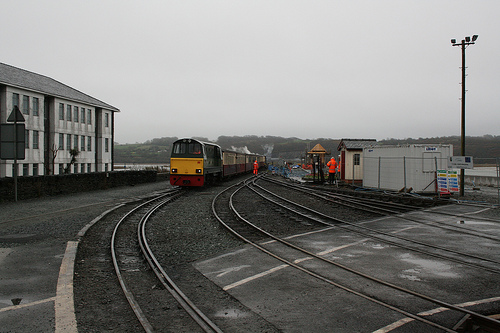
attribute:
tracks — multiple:
[68, 168, 498, 324]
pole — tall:
[459, 41, 467, 195]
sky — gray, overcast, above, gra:
[7, 2, 499, 140]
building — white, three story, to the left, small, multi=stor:
[4, 60, 122, 181]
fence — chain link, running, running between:
[0, 163, 164, 202]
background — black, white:
[3, 5, 497, 219]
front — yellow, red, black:
[166, 135, 205, 189]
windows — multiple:
[4, 87, 117, 175]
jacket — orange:
[326, 160, 339, 174]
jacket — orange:
[255, 158, 259, 169]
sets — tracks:
[83, 169, 499, 322]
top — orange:
[324, 156, 340, 173]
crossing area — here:
[7, 191, 500, 330]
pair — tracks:
[110, 195, 231, 329]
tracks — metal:
[107, 184, 218, 332]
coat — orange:
[326, 156, 337, 174]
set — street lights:
[451, 34, 486, 49]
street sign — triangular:
[6, 104, 31, 122]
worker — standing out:
[248, 156, 261, 178]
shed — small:
[339, 134, 381, 180]